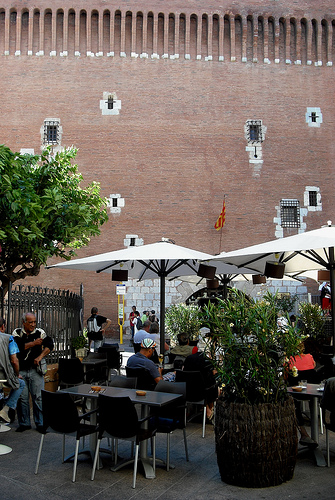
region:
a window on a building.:
[216, 113, 279, 168]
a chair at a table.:
[81, 390, 143, 485]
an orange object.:
[281, 344, 322, 376]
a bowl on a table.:
[129, 382, 148, 401]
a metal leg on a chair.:
[62, 434, 87, 485]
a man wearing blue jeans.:
[5, 306, 59, 434]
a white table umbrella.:
[32, 235, 217, 280]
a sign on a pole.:
[105, 278, 133, 347]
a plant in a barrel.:
[201, 338, 306, 490]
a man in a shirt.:
[3, 302, 65, 424]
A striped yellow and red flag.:
[203, 189, 230, 257]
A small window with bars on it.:
[273, 193, 300, 229]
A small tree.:
[193, 290, 303, 485]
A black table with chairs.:
[30, 371, 194, 479]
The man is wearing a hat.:
[134, 330, 160, 359]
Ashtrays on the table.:
[85, 378, 147, 397]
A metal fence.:
[0, 278, 82, 360]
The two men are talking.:
[0, 305, 56, 440]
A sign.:
[108, 277, 126, 344]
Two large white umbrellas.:
[47, 205, 331, 340]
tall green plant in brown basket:
[200, 285, 306, 488]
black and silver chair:
[86, 392, 141, 498]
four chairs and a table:
[35, 367, 180, 475]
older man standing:
[11, 304, 56, 417]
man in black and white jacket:
[13, 312, 51, 379]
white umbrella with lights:
[90, 230, 180, 373]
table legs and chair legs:
[54, 436, 176, 491]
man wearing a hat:
[105, 335, 169, 383]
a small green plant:
[54, 323, 93, 356]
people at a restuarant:
[0, 324, 201, 475]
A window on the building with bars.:
[276, 197, 306, 230]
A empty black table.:
[33, 376, 197, 444]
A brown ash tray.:
[126, 386, 155, 399]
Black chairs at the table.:
[37, 389, 87, 451]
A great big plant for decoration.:
[166, 290, 329, 496]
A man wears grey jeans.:
[17, 366, 47, 425]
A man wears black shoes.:
[12, 418, 51, 434]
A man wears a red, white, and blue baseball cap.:
[135, 336, 160, 348]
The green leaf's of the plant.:
[203, 301, 303, 373]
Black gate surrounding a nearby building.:
[49, 288, 80, 348]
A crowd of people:
[1, 291, 199, 437]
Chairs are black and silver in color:
[27, 386, 153, 494]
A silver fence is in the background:
[6, 279, 88, 364]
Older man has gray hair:
[8, 310, 43, 337]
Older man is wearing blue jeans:
[13, 366, 47, 426]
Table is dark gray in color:
[58, 377, 186, 423]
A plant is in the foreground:
[202, 290, 305, 495]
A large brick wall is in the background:
[0, 15, 333, 233]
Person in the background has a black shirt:
[81, 303, 111, 341]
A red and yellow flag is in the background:
[198, 191, 233, 257]